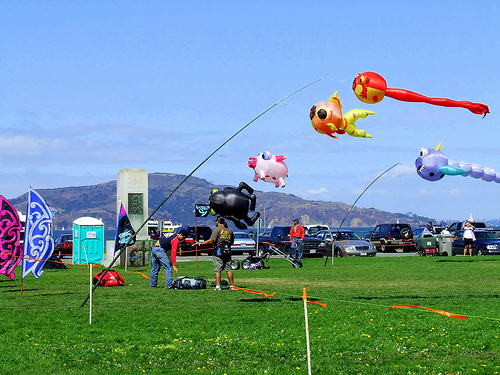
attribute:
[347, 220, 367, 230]
water — in front of the mountain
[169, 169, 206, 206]
hill — in background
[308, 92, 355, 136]
kite — airborne, colorful, yellow, blue, fish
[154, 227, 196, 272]
man — bent, standing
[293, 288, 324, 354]
post — supporting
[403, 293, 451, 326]
streamers — orange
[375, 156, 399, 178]
banner — blue, fancy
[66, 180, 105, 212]
mountain — tall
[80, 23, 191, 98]
sky — blue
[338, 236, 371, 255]
car — silver, parked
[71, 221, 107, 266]
port a potty — blue, portable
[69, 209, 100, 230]
roof — white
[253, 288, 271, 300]
flag — orange, blue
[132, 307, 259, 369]
field — grassy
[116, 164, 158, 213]
structure — white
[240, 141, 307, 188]
kite — pig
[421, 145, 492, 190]
balloon — floating, purple, character, colorful